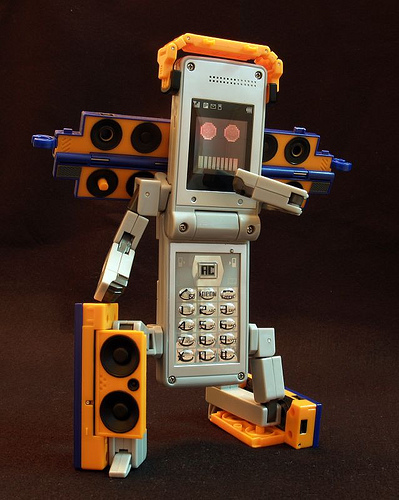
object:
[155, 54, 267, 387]
cell phone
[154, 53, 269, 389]
phone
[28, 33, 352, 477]
robot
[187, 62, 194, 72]
screw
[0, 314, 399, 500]
table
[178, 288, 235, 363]
button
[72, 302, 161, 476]
leg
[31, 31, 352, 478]
robot phone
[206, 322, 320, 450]
leg